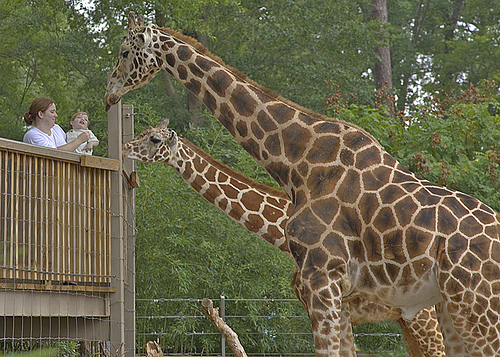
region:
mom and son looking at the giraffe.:
[23, 95, 98, 159]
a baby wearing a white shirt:
[66, 108, 99, 153]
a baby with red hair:
[63, 109, 99, 161]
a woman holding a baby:
[23, 97, 98, 154]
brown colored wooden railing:
[1, 135, 109, 292]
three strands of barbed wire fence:
[141, 294, 404, 355]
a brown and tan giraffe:
[100, 8, 497, 350]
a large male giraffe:
[103, 10, 498, 354]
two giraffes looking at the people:
[103, 8, 497, 355]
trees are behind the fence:
[1, 3, 496, 352]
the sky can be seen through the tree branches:
[56, 0, 482, 123]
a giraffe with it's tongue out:
[99, 7, 498, 355]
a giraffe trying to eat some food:
[116, 111, 471, 353]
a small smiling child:
[66, 107, 102, 157]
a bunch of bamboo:
[3, 55, 313, 352]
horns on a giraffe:
[127, 8, 149, 36]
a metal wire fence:
[133, 287, 461, 355]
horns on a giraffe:
[153, 115, 181, 132]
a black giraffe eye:
[119, 45, 131, 59]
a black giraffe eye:
[148, 131, 160, 143]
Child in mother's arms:
[63, 110, 98, 155]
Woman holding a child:
[18, 97, 75, 157]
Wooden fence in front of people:
[0, 138, 111, 284]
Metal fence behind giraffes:
[138, 298, 416, 352]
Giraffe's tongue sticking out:
[103, 103, 110, 109]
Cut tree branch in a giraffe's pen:
[201, 298, 248, 353]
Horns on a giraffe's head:
[125, 11, 148, 26]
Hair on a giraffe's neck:
[166, 25, 354, 132]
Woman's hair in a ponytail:
[21, 110, 32, 125]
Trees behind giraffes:
[1, 2, 499, 305]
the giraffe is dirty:
[260, 123, 470, 287]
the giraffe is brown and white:
[290, 116, 442, 266]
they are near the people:
[2, 25, 207, 243]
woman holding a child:
[60, 104, 99, 167]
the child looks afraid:
[65, 109, 96, 126]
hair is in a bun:
[20, 95, 45, 119]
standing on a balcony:
[0, 60, 91, 324]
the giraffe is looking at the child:
[116, 116, 198, 176]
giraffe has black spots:
[275, 138, 405, 274]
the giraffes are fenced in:
[109, 249, 434, 348]